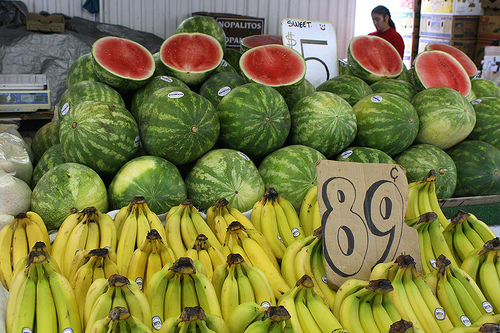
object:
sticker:
[218, 86, 232, 97]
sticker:
[61, 327, 74, 332]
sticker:
[135, 276, 143, 289]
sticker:
[151, 316, 162, 330]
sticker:
[260, 301, 270, 308]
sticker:
[291, 227, 301, 237]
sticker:
[482, 300, 494, 313]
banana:
[0, 170, 499, 333]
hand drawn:
[320, 175, 369, 277]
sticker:
[21, 327, 32, 333]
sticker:
[277, 235, 284, 242]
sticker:
[321, 276, 328, 284]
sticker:
[434, 307, 446, 320]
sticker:
[460, 315, 472, 327]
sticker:
[429, 258, 438, 268]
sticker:
[472, 99, 481, 105]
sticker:
[370, 95, 383, 103]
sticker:
[340, 149, 353, 159]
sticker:
[238, 151, 250, 161]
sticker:
[221, 60, 227, 67]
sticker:
[160, 76, 173, 83]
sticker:
[134, 135, 140, 147]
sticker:
[61, 103, 70, 115]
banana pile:
[1, 164, 498, 331]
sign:
[314, 159, 426, 292]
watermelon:
[28, 15, 500, 231]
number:
[321, 175, 368, 276]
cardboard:
[316, 160, 424, 291]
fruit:
[237, 37, 310, 89]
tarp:
[18, 21, 106, 109]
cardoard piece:
[315, 159, 423, 292]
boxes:
[391, 0, 498, 85]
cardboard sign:
[315, 159, 425, 288]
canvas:
[6, 27, 79, 80]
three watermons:
[91, 32, 307, 95]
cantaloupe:
[0, 172, 32, 216]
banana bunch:
[2, 242, 86, 332]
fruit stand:
[5, 25, 497, 328]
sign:
[280, 18, 339, 89]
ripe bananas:
[6, 212, 489, 326]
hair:
[372, 5, 396, 31]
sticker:
[168, 91, 185, 99]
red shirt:
[367, 31, 404, 60]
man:
[365, 5, 403, 61]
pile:
[19, 19, 498, 216]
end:
[170, 256, 201, 277]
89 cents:
[321, 166, 404, 278]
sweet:
[287, 20, 312, 28]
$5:
[281, 31, 330, 83]